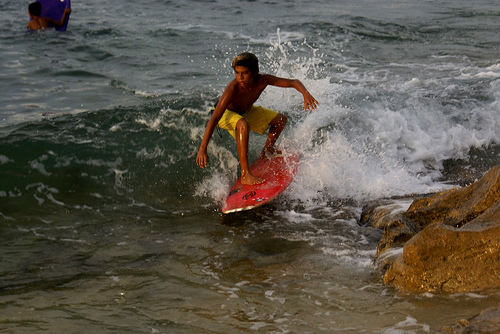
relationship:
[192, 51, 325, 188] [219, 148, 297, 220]
boy on top of surfboard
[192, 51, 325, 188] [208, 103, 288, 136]
boy wearing shorts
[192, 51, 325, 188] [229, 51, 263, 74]
boy has hair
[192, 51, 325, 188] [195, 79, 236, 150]
boy has arm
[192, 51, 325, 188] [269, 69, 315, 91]
boy has arm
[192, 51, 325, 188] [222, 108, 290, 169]
boy has legs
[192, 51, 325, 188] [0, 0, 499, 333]
boy splashing ocean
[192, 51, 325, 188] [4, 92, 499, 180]
boy riding wave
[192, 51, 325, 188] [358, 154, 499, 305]
boy near boulder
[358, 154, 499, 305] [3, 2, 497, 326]
boulder inside ocean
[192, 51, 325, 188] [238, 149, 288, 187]
boy has feet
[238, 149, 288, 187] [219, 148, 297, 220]
feet on top of surfboard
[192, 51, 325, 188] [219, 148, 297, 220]
boy has surfboard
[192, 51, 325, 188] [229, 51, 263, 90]
boy has head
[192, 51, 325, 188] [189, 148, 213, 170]
boy has hand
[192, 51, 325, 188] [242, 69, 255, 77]
boy has eye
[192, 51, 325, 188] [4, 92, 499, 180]
boy in front of wave